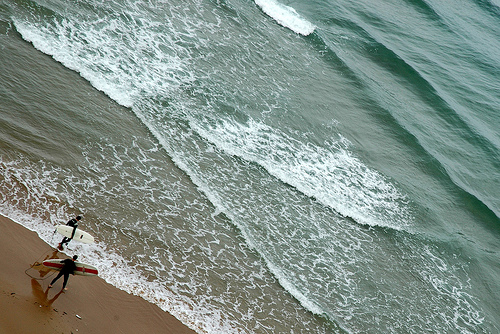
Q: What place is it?
A: It is a sea.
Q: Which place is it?
A: It is a sea.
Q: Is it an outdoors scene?
A: Yes, it is outdoors.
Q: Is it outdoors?
A: Yes, it is outdoors.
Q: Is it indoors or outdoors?
A: It is outdoors.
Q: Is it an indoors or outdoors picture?
A: It is outdoors.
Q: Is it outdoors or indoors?
A: It is outdoors.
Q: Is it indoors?
A: No, it is outdoors.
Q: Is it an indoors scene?
A: No, it is outdoors.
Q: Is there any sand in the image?
A: Yes, there is sand.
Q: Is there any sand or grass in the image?
A: Yes, there is sand.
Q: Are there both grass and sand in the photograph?
A: No, there is sand but no grass.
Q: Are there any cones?
A: No, there are no cones.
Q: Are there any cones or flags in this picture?
A: No, there are no cones or flags.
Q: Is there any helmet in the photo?
A: No, there are no helmets.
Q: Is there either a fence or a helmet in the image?
A: No, there are no helmets or fences.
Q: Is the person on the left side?
A: Yes, the person is on the left of the image.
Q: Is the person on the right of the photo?
A: No, the person is on the left of the image.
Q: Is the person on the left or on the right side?
A: The person is on the left of the image.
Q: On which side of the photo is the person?
A: The person is on the left of the image.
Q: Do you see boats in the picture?
A: No, there are no boats.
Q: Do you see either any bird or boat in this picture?
A: No, there are no boats or birds.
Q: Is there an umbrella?
A: No, there are no umbrellas.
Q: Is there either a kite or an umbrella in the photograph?
A: No, there are no umbrellas or kites.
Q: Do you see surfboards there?
A: Yes, there is a surfboard.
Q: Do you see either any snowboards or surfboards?
A: Yes, there is a surfboard.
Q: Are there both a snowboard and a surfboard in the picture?
A: No, there is a surfboard but no snowboards.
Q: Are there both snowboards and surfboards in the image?
A: No, there is a surfboard but no snowboards.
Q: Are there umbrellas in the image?
A: No, there are no umbrellas.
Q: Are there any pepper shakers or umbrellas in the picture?
A: No, there are no umbrellas or pepper shakers.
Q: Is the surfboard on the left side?
A: Yes, the surfboard is on the left of the image.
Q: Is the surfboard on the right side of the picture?
A: No, the surfboard is on the left of the image.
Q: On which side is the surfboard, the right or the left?
A: The surfboard is on the left of the image.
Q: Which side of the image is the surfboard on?
A: The surfboard is on the left of the image.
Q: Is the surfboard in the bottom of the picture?
A: Yes, the surfboard is in the bottom of the image.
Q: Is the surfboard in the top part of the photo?
A: No, the surfboard is in the bottom of the image.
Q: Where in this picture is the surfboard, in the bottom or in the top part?
A: The surfboard is in the bottom of the image.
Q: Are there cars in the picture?
A: No, there are no cars.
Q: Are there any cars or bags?
A: No, there are no cars or bags.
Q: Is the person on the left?
A: Yes, the person is on the left of the image.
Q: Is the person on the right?
A: No, the person is on the left of the image.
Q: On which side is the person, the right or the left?
A: The person is on the left of the image.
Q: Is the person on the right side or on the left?
A: The person is on the left of the image.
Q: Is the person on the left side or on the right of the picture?
A: The person is on the left of the image.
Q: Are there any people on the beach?
A: Yes, there is a person on the beach.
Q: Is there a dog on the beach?
A: No, there is a person on the beach.